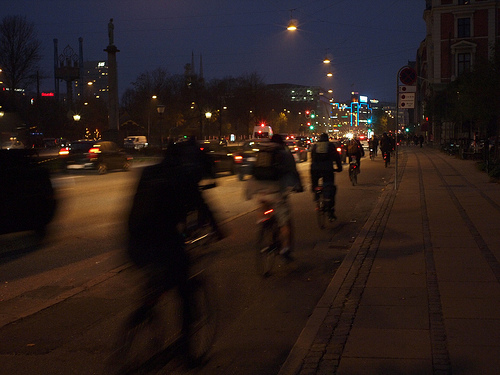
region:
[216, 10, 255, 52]
The sky is blue.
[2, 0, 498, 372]
The picture is taken a t night.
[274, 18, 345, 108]
A row of lights.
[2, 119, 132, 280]
Cars are on the road.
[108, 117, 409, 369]
People are riding bikes.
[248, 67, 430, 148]
Buildings are in the distance.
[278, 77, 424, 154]
Lights are on the buildings.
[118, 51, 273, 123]
Trees are in the background.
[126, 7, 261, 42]
The sky is clear.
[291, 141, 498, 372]
A sidewalk.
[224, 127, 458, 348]
people biking on street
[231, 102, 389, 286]
people biking on street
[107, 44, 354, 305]
people biking on street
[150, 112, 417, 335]
people riding bikes in the bike lane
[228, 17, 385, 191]
people riding bikes in traffic at night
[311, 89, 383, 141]
blue neon lights in the distance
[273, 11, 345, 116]
street lights are on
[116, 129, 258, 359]
cyclist in the foreground is blurry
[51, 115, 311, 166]
cars and traffic on the left of the cyclists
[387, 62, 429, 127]
dimly illuminated traffic sign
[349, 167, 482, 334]
empty sidewalk and curb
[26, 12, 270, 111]
tall steeples in the distance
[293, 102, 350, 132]
red and green traffic lights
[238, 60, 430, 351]
people on road bikes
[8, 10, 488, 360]
a city scene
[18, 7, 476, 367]
nighttime in the city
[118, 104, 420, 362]
people are riding bicycles on the road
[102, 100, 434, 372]
the bicyclists are riding along a curbside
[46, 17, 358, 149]
the streetlights are on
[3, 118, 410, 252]
cars are on the road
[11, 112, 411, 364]
both cars and bicycles are on the road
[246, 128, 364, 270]
the people on bicycles are wearing backpacks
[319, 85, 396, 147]
a building with neon lights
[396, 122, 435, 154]
people are on the sidewalk